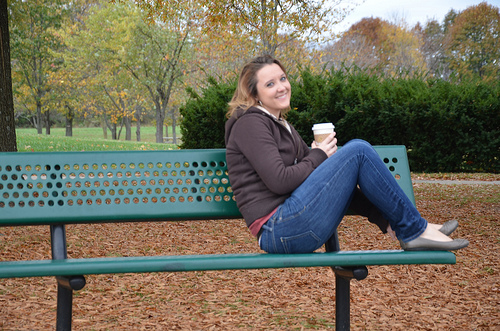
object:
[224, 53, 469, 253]
woman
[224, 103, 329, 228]
sweater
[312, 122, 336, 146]
cup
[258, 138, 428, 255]
jeans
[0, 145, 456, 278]
bench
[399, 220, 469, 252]
flats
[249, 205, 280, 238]
shirt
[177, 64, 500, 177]
bushes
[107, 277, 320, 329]
leaves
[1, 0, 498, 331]
park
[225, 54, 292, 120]
hair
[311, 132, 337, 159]
hand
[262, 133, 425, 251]
legs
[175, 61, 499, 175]
hedge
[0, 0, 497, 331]
background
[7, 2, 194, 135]
trees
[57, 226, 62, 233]
metal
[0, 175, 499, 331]
ground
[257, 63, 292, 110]
face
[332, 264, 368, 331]
leg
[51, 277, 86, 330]
leg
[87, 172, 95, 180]
holes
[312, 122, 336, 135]
lid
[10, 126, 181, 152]
grass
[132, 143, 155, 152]
leaves